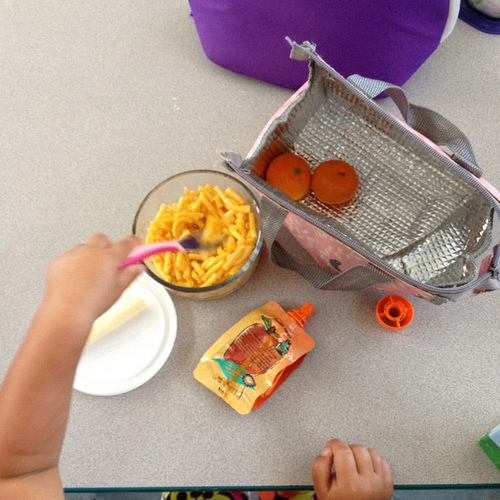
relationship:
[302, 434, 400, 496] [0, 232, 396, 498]
hand of a person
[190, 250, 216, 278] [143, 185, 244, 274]
cheese in bowl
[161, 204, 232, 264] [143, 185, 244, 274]
mac in bowl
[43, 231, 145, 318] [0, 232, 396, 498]
hands of person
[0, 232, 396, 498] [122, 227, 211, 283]
person holding spoon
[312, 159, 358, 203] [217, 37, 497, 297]
orange in a cooler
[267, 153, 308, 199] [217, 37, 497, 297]
orange in a cooler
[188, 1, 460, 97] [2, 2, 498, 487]
cooler on a table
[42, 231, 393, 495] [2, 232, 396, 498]
hands of a person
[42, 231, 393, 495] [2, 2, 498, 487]
hands above a table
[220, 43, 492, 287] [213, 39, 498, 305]
inside of a tote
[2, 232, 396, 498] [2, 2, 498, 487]
person at a table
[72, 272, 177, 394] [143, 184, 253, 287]
lid on mac cheese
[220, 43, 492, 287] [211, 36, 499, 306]
inside of picnic pack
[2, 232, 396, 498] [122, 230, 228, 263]
person holding a fork